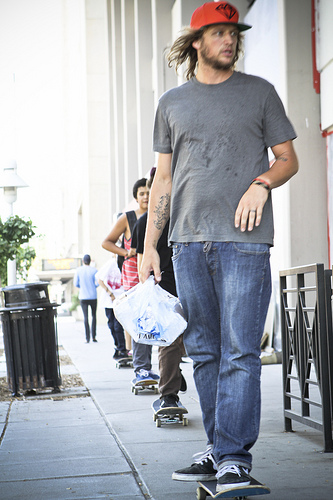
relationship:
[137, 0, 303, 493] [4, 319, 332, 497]
man down sidewalk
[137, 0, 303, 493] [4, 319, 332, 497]
man skateboarding down sidewalk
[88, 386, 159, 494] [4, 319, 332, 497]
crack in sidewalk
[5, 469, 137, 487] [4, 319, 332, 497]
crack in sidewalk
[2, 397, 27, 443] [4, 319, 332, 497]
crack in sidewalk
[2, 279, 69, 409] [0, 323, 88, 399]
trashcan on side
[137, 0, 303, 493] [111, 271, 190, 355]
man holding bag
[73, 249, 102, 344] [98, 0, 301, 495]
person away from group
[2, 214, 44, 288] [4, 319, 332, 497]
tree beside sidewalk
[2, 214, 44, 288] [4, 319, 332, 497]
tree growing beside sidewalk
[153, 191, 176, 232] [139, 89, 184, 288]
tattoo on arm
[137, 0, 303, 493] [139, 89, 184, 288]
man has arm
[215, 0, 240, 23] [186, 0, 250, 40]
diamond on hat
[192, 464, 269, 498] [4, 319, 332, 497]
skateboard on sidewalk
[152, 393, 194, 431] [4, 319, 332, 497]
skateboard on sidewalk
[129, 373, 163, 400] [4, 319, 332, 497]
skateboard on sidewalk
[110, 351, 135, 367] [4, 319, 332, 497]
skateboard on sidewalk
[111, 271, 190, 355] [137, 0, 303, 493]
bag held by man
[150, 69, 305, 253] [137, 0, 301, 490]
tshirt worn by man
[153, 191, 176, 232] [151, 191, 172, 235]
tattoo on tattoo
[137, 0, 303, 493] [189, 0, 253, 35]
man in hat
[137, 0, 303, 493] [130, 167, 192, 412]
man leading person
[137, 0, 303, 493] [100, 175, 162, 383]
man leading boy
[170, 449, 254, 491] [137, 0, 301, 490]
sneakers worn by man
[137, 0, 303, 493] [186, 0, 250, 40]
man wearing hat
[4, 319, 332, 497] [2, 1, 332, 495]
sidewalk in city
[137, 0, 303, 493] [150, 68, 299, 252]
man wearing tshirt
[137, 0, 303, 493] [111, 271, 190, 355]
man carrying bag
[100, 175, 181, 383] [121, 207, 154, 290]
boy with shirt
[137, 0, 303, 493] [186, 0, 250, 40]
man has hat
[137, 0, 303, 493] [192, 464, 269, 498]
man riding skateboard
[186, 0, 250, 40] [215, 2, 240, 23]
hat has diamond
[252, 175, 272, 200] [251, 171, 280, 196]
bracelet on wrist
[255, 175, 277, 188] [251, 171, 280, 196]
bracelet on wrist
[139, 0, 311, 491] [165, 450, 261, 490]
he wears vans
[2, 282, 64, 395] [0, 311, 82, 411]
garbage can on edge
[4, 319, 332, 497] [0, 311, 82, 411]
sidewalk has edge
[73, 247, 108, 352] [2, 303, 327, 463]
person down street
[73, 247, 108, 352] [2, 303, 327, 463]
person walking down street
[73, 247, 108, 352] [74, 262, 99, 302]
person wearing tshirt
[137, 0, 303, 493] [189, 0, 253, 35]
man wearing hat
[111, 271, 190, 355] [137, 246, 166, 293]
bag on hand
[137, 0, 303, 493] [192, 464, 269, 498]
man on skateboard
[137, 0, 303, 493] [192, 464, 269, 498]
person on skateboard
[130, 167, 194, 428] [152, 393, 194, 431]
person on skateboard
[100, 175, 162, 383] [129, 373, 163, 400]
boy on skateboard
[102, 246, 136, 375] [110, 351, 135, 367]
person on skateboard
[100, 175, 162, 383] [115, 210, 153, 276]
boy wearing backpack